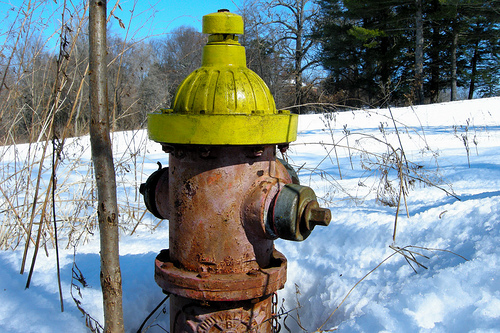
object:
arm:
[272, 184, 331, 241]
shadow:
[54, 251, 161, 294]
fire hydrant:
[138, 8, 331, 333]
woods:
[0, 1, 498, 145]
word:
[197, 310, 257, 331]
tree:
[269, 0, 323, 107]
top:
[146, 8, 297, 145]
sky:
[0, 1, 206, 31]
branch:
[380, 240, 439, 273]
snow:
[0, 89, 484, 322]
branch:
[334, 131, 464, 207]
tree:
[85, 1, 125, 333]